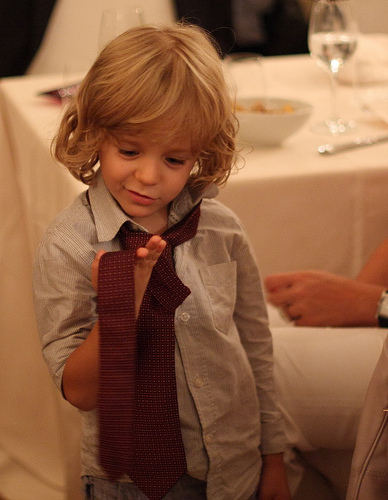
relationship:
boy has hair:
[32, 23, 290, 499] [50, 23, 250, 195]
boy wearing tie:
[32, 23, 290, 499] [97, 208, 202, 498]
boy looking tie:
[32, 23, 290, 499] [97, 208, 202, 498]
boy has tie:
[32, 23, 290, 499] [97, 208, 202, 498]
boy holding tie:
[32, 23, 290, 499] [97, 208, 202, 498]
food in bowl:
[233, 98, 299, 114] [233, 93, 314, 151]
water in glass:
[306, 33, 359, 71] [307, 0, 360, 135]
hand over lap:
[264, 269, 387, 327] [271, 324, 387, 497]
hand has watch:
[264, 269, 387, 327] [375, 288, 387, 330]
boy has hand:
[32, 23, 290, 499] [64, 234, 167, 413]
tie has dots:
[97, 208, 202, 498] [99, 206, 201, 496]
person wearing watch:
[268, 237, 387, 496] [375, 288, 387, 330]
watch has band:
[375, 288, 387, 330] [377, 310, 387, 333]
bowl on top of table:
[233, 93, 314, 151] [3, 54, 388, 499]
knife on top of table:
[316, 135, 388, 155] [3, 54, 388, 499]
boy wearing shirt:
[32, 23, 290, 499] [35, 171, 287, 500]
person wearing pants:
[268, 237, 387, 496] [269, 327, 383, 494]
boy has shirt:
[32, 23, 290, 499] [35, 171, 287, 500]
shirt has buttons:
[35, 171, 287, 500] [178, 310, 217, 446]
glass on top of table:
[307, 0, 360, 135] [3, 54, 388, 499]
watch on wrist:
[375, 288, 387, 330] [363, 287, 388, 326]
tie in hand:
[97, 208, 202, 498] [64, 234, 167, 413]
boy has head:
[32, 23, 290, 499] [50, 20, 244, 219]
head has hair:
[50, 20, 244, 219] [50, 23, 250, 195]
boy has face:
[32, 23, 290, 499] [101, 105, 205, 219]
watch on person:
[375, 288, 387, 330] [268, 237, 387, 496]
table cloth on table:
[3, 32, 387, 498] [3, 54, 388, 499]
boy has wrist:
[32, 23, 290, 499] [265, 452, 288, 471]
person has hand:
[268, 237, 387, 496] [264, 269, 387, 327]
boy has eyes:
[32, 23, 290, 499] [114, 145, 188, 168]